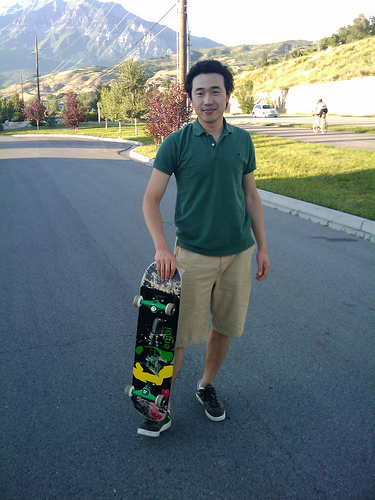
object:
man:
[138, 62, 267, 439]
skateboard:
[124, 261, 182, 422]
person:
[313, 98, 328, 117]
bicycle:
[313, 119, 328, 134]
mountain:
[0, 0, 227, 77]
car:
[252, 103, 278, 118]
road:
[0, 136, 374, 498]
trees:
[119, 59, 147, 134]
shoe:
[196, 384, 226, 421]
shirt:
[153, 118, 256, 257]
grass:
[255, 139, 375, 222]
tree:
[63, 91, 84, 133]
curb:
[257, 189, 375, 241]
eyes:
[196, 92, 203, 95]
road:
[224, 113, 374, 151]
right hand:
[155, 250, 177, 281]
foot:
[137, 410, 171, 437]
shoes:
[137, 410, 171, 438]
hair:
[185, 60, 234, 100]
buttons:
[211, 143, 215, 147]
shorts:
[173, 242, 255, 346]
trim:
[138, 417, 171, 436]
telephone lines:
[86, 2, 175, 86]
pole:
[178, 0, 189, 120]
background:
[0, 0, 374, 150]